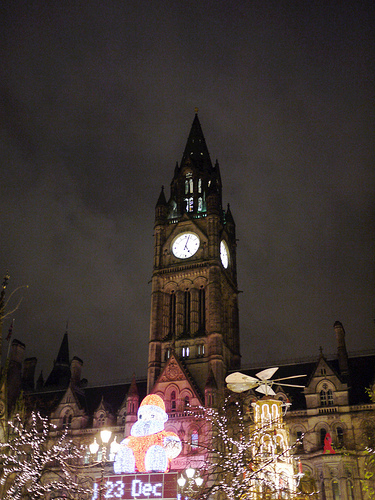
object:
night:
[233, 35, 342, 161]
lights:
[0, 410, 97, 498]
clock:
[217, 237, 231, 272]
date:
[87, 479, 164, 499]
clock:
[171, 232, 199, 261]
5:
[184, 246, 196, 256]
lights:
[174, 387, 318, 500]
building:
[147, 113, 243, 399]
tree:
[0, 410, 92, 497]